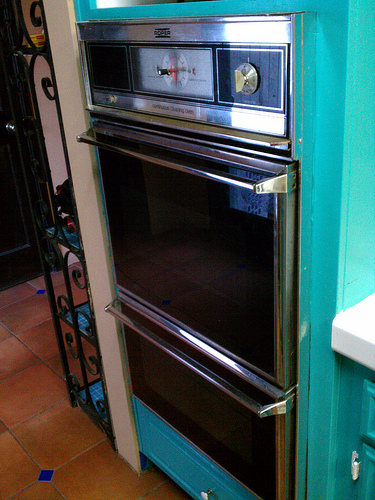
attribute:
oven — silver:
[88, 116, 323, 382]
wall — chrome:
[81, 5, 369, 499]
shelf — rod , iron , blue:
[13, 1, 111, 462]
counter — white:
[324, 294, 372, 391]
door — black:
[3, 4, 56, 291]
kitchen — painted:
[4, 0, 373, 499]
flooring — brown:
[0, 266, 189, 499]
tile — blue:
[40, 467, 54, 484]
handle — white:
[197, 485, 211, 499]